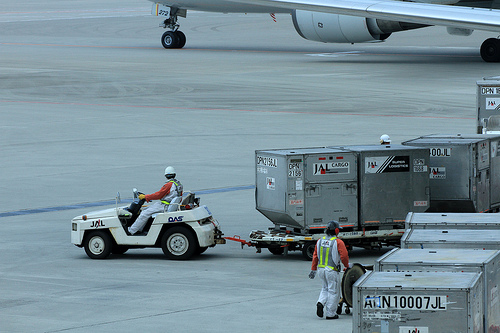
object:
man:
[125, 166, 184, 236]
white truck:
[68, 201, 221, 260]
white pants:
[128, 200, 164, 235]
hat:
[164, 166, 176, 176]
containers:
[255, 147, 358, 232]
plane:
[148, 0, 499, 63]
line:
[0, 183, 257, 217]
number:
[364, 295, 446, 308]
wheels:
[160, 30, 187, 49]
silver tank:
[352, 270, 484, 332]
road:
[2, 2, 499, 332]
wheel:
[159, 224, 197, 260]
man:
[308, 219, 350, 320]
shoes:
[316, 302, 324, 319]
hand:
[308, 270, 318, 279]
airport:
[0, 0, 500, 333]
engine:
[290, 9, 394, 46]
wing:
[266, 0, 500, 31]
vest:
[316, 235, 339, 270]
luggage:
[403, 211, 499, 228]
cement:
[2, 1, 499, 76]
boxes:
[353, 211, 499, 333]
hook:
[220, 235, 252, 246]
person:
[379, 134, 392, 145]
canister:
[328, 144, 431, 231]